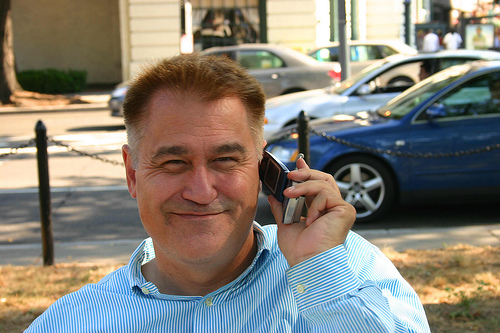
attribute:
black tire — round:
[321, 151, 396, 222]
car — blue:
[261, 56, 499, 227]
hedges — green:
[10, 65, 88, 94]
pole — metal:
[32, 117, 61, 265]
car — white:
[281, 41, 461, 112]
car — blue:
[321, 67, 472, 149]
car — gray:
[100, 43, 342, 120]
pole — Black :
[33, 117, 56, 267]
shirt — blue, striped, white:
[14, 218, 429, 331]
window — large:
[151, 10, 303, 71]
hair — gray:
[129, 116, 145, 167]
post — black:
[29, 118, 58, 265]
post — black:
[295, 109, 308, 168]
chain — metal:
[2, 109, 497, 167]